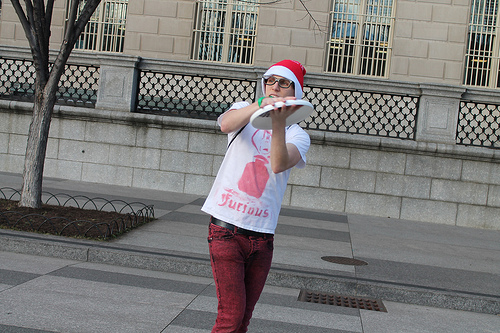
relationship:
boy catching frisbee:
[207, 59, 311, 333] [248, 95, 317, 129]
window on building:
[192, 0, 257, 62] [10, 4, 499, 224]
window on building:
[459, 0, 499, 86] [1, 0, 496, 149]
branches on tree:
[10, 0, 103, 88] [9, 0, 101, 207]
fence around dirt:
[20, 209, 105, 246] [65, 210, 99, 218]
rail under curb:
[297, 289, 387, 312] [0, 220, 497, 318]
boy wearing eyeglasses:
[197, 55, 313, 331] [259, 72, 296, 89]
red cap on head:
[262, 57, 307, 100] [257, 53, 309, 117]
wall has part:
[0, 46, 500, 231] [419, 192, 433, 212]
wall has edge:
[0, 46, 498, 228] [364, 132, 380, 150]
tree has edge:
[20, 8, 74, 188] [41, 97, 51, 177]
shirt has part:
[200, 102, 311, 235] [228, 183, 237, 193]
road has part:
[344, 243, 420, 295] [368, 263, 388, 277]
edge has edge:
[0, 231, 500, 316] [322, 272, 349, 288]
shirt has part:
[190, 98, 311, 249] [235, 217, 249, 226]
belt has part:
[208, 214, 273, 239] [215, 217, 231, 231]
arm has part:
[260, 109, 312, 179] [268, 146, 275, 151]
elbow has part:
[270, 158, 287, 177] [273, 164, 282, 174]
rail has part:
[341, 295, 351, 304] [346, 297, 358, 304]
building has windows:
[10, 4, 499, 224] [61, 0, 498, 87]